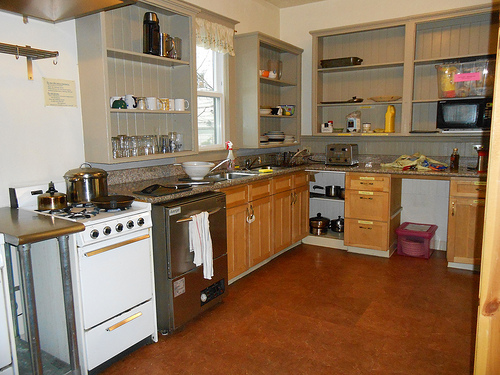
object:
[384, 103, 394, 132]
jug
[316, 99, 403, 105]
shelf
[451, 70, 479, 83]
label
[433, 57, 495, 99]
container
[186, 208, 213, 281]
towel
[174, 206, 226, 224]
rack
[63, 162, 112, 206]
cooker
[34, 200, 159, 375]
stove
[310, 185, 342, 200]
cooker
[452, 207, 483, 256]
cabinet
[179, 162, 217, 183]
bowl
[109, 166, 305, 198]
counter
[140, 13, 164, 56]
thermos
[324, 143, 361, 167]
toaster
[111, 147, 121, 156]
glass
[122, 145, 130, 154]
glass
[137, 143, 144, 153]
glass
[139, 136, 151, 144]
glass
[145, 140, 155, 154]
glass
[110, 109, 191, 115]
shelf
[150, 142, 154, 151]
glass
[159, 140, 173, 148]
glass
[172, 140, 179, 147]
glass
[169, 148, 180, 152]
glass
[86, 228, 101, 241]
knob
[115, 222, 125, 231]
knob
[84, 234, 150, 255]
handle